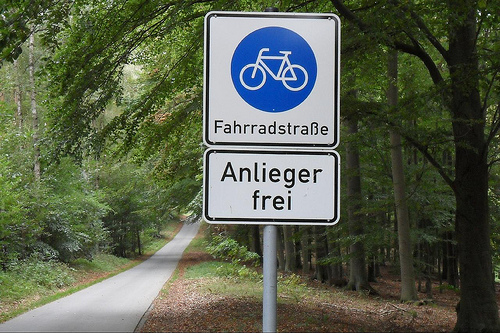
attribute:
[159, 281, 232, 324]
ground — full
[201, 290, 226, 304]
leave — brown, green, dry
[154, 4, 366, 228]
sign — board, white, pole, outline, blue, german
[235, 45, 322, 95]
bicycle — white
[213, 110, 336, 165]
path — bike, walking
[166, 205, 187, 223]
light — sun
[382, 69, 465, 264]
tree — barked, trunk, row, tall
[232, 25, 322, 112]
circle — blue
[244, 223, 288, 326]
pole — tall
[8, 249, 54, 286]
bush — green